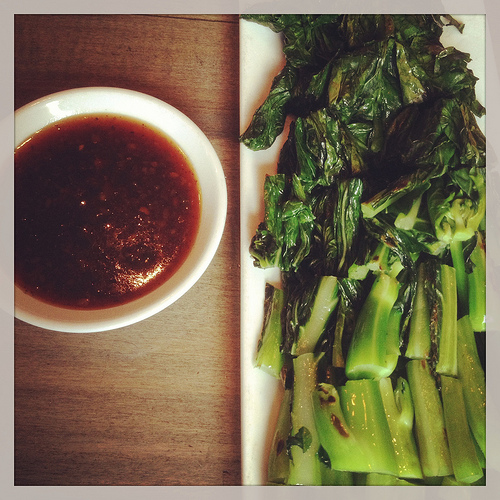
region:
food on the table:
[0, 77, 479, 483]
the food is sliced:
[362, 294, 478, 476]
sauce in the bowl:
[12, 108, 212, 318]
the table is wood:
[63, 375, 170, 457]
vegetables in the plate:
[271, 116, 471, 497]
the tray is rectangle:
[221, 83, 429, 496]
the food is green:
[297, 59, 433, 263]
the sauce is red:
[80, 182, 170, 268]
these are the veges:
[314, 51, 463, 314]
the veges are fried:
[305, 115, 467, 377]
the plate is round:
[206, 175, 228, 206]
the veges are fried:
[296, 50, 472, 322]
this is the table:
[67, 357, 207, 488]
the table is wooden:
[98, 330, 203, 474]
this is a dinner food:
[34, 36, 426, 433]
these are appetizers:
[43, 113, 496, 425]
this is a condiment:
[7, 122, 224, 309]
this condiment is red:
[30, 134, 244, 305]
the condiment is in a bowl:
[40, 141, 229, 403]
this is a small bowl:
[45, 261, 180, 371]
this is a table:
[65, 370, 240, 480]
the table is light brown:
[55, 350, 194, 492]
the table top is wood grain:
[48, 364, 212, 464]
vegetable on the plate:
[338, 380, 396, 482]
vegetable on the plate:
[397, 364, 449, 448]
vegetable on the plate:
[420, 371, 472, 469]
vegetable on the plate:
[226, 279, 277, 353]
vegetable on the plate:
[340, 266, 404, 368]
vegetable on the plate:
[408, 274, 473, 363]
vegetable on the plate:
[390, 169, 446, 254]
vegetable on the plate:
[315, 94, 352, 174]